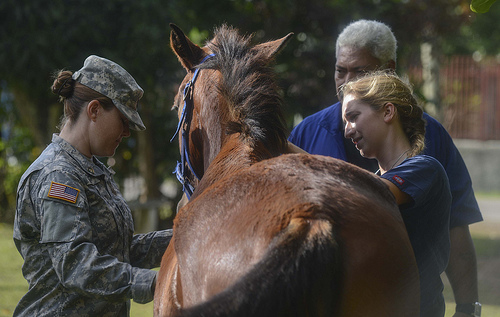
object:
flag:
[43, 182, 88, 204]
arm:
[36, 182, 159, 292]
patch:
[38, 204, 77, 242]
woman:
[24, 53, 173, 316]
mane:
[208, 23, 284, 149]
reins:
[183, 123, 202, 194]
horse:
[153, 22, 426, 316]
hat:
[73, 55, 156, 132]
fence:
[450, 62, 486, 142]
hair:
[353, 69, 427, 157]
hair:
[335, 17, 398, 63]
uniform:
[12, 133, 175, 315]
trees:
[28, 14, 142, 48]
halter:
[166, 159, 202, 198]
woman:
[334, 70, 462, 317]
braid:
[402, 94, 429, 155]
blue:
[307, 128, 334, 150]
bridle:
[171, 50, 216, 202]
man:
[290, 14, 485, 316]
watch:
[461, 300, 485, 314]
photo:
[4, 4, 497, 315]